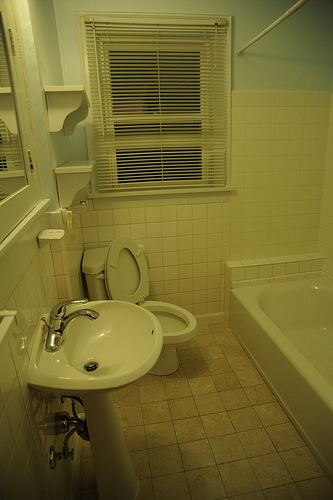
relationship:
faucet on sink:
[39, 291, 101, 328] [29, 293, 163, 393]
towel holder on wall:
[65, 209, 84, 245] [10, 6, 88, 385]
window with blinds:
[80, 13, 239, 197] [89, 22, 228, 185]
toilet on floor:
[85, 239, 199, 378] [82, 317, 332, 493]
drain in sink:
[79, 361, 101, 372] [29, 293, 163, 393]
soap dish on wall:
[39, 228, 74, 251] [10, 6, 88, 385]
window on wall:
[80, 13, 239, 197] [48, 2, 331, 352]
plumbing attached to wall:
[45, 393, 92, 471] [10, 6, 88, 385]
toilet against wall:
[85, 239, 199, 378] [10, 6, 88, 385]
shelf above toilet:
[44, 78, 89, 136] [85, 239, 199, 378]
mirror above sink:
[3, 7, 28, 227] [29, 293, 163, 393]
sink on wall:
[29, 293, 163, 393] [48, 2, 331, 352]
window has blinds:
[80, 13, 239, 197] [89, 22, 228, 185]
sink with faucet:
[29, 293, 163, 393] [39, 291, 101, 328]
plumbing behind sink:
[45, 393, 92, 471] [29, 293, 163, 393]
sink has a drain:
[29, 293, 163, 393] [79, 361, 101, 372]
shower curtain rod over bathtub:
[233, 5, 307, 60] [230, 277, 332, 454]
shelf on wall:
[44, 78, 89, 136] [10, 6, 88, 385]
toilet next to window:
[85, 239, 199, 378] [80, 13, 239, 197]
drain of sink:
[79, 361, 101, 372] [29, 293, 163, 393]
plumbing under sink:
[45, 393, 92, 471] [29, 293, 163, 393]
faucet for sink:
[39, 291, 101, 328] [29, 293, 163, 393]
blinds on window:
[89, 22, 228, 185] [80, 13, 239, 197]